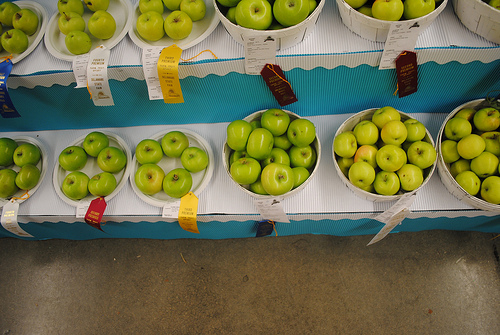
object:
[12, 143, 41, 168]
apples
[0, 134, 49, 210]
plate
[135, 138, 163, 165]
apples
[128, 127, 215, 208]
plate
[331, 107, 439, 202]
bucket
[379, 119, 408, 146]
apple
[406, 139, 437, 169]
apple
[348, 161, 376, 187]
apple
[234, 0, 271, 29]
apple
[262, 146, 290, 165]
apple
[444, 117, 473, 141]
apple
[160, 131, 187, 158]
apple